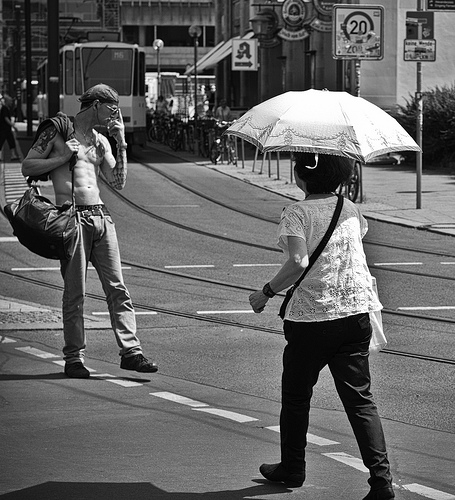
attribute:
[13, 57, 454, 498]
people — some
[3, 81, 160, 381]
people — some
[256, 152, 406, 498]
person — in the sunshine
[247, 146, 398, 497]
person — shirtless